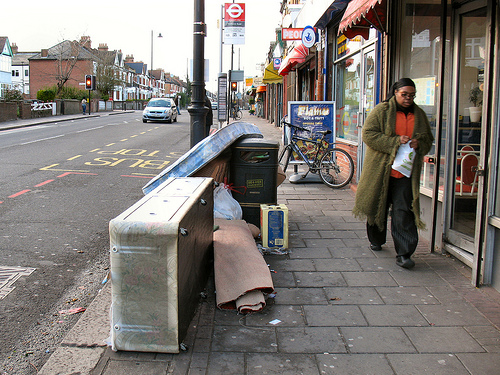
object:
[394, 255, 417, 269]
shoe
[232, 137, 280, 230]
trash can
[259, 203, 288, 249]
trash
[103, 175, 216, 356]
trash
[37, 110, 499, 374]
sidewalk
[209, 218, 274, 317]
carpet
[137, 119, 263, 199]
mattress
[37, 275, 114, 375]
curb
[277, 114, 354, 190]
bicycle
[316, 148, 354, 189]
tire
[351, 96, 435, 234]
coat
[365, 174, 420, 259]
pants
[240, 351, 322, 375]
block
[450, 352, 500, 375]
block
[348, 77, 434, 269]
woman